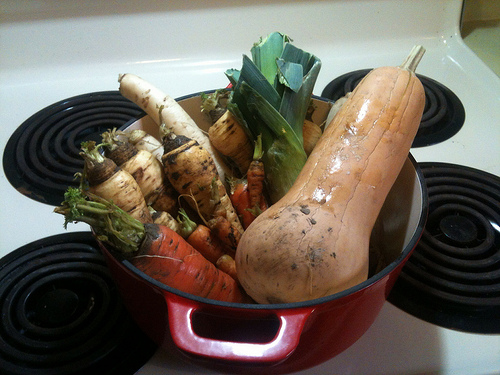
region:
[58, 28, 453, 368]
large metal pot full of vegetables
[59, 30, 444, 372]
red metal pot full of uncooked food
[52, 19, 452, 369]
pot of dirty vegetables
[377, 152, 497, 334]
coil type burner of electric stove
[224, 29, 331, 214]
green leafy vegetable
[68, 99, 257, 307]
several types of root vegetable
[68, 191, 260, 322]
orange carrot with green leafy top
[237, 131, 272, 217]
tiny carrot like vegetable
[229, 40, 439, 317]
vegetable that is a member of the squash family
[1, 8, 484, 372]
large pot of vegetables sitting on a stove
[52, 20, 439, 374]
the veggies are in the pot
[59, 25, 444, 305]
the veggies are dirty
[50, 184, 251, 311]
this carrot is orange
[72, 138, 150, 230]
this parsnip is dirty and white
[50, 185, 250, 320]
this is a carrot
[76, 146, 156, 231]
this is a parsnip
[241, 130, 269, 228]
this carrot is very small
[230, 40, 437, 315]
this squash is dirty and wet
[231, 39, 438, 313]
this squash is very large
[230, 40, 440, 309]
this is a squash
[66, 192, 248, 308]
this is a root vegetable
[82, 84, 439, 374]
this is a pot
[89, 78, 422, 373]
this pot is red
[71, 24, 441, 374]
this pot has many veggies in it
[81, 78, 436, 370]
this pot is on the stove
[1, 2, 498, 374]
the stove is white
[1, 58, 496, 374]
the stove has 4 burners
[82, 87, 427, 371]
red pot on a stove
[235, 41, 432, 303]
fresh squash in a pan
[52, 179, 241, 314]
fresh carrot in a pan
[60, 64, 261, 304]
root vegetables in a pan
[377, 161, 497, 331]
stove top burner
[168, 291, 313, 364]
handle of a red pot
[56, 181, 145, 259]
top leaf of a carrot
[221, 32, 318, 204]
artichoke plant in the pot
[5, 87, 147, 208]
upper left stovetop burner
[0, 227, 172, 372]
bottom left stovetop burner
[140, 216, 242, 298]
raw carrot in a red pot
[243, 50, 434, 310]
butternut squash in a red pot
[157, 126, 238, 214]
raw turnip in a red pot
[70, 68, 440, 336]
raw vegetables in a red pot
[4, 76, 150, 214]
black burner on the back of the stove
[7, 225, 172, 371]
black burner at the front of the stove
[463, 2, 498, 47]
counter beside the stove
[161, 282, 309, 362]
handle on a red pot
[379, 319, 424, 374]
white metal surface of the stove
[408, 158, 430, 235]
rim of the red pot